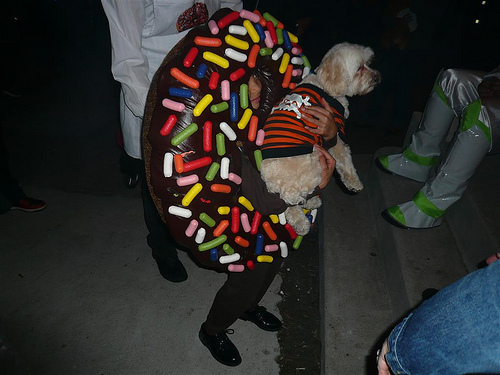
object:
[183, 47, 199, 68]
confection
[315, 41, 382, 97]
head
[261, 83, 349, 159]
t-shirt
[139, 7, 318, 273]
costume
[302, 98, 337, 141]
hand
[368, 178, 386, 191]
ground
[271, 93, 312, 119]
skull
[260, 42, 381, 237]
dog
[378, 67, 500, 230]
plastic footwear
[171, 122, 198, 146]
sprinkle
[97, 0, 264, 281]
person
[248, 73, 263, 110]
face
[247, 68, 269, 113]
hole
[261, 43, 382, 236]
fur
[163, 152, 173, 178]
sprinkle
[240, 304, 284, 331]
shoe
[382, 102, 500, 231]
shoe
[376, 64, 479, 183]
shoe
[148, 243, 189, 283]
shoe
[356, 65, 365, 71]
eye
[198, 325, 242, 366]
shoe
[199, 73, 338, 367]
boy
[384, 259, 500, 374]
denim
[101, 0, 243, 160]
apron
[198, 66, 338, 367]
lady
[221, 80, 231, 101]
sprinkle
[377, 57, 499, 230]
person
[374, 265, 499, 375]
surface